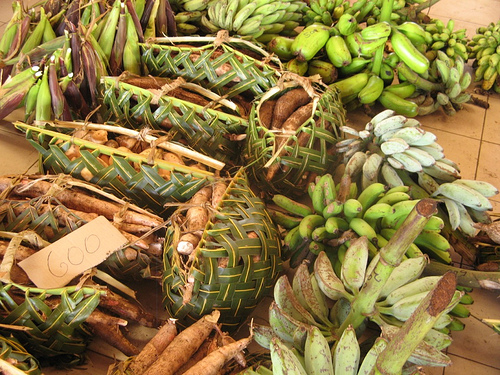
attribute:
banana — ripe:
[348, 224, 380, 243]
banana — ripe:
[341, 189, 360, 211]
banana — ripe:
[368, 199, 390, 222]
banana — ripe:
[388, 196, 423, 226]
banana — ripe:
[296, 211, 316, 240]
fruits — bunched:
[249, 172, 471, 374]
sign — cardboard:
[12, 215, 128, 300]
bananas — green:
[317, 194, 364, 233]